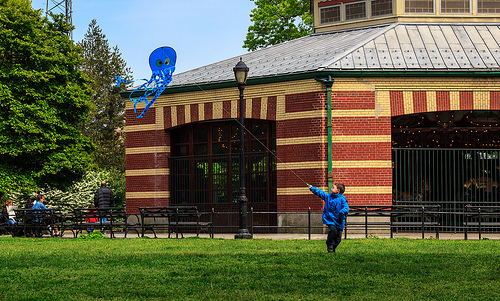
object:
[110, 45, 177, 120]
kite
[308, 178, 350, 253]
kid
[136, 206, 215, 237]
benches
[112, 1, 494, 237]
house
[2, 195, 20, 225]
people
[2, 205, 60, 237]
bench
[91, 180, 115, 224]
adult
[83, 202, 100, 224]
child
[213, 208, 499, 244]
fence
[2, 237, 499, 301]
field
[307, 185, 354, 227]
jacket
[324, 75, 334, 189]
pipe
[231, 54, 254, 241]
lamp post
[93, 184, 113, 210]
black jacket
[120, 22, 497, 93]
roof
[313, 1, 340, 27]
window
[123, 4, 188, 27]
air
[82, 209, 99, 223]
red coat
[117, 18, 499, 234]
pavillion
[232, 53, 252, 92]
light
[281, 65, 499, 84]
gutter